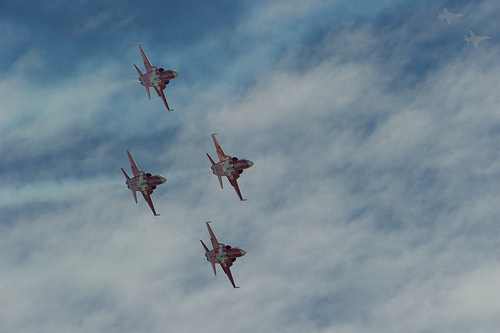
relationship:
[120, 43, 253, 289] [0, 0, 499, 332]
jets in sky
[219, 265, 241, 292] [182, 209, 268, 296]
wing on plane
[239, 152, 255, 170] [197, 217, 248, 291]
nose on plane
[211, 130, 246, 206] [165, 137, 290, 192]
wings on plane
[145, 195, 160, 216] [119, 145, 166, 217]
right wing on plane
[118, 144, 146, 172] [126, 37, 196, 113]
wing on plane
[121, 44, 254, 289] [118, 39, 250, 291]
jets flying angle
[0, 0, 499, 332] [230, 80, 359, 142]
sky full cloud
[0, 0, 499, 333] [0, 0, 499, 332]
cloud in sky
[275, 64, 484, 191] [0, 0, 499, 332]
cloud in sky